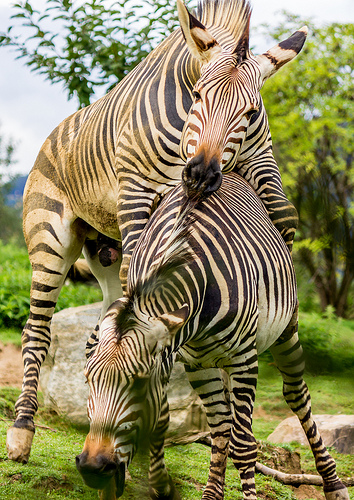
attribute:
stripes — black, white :
[45, 61, 200, 207]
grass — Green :
[7, 378, 287, 487]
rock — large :
[41, 299, 183, 436]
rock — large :
[45, 279, 215, 435]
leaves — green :
[304, 312, 327, 355]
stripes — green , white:
[150, 190, 272, 410]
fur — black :
[139, 298, 188, 391]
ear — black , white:
[144, 258, 215, 420]